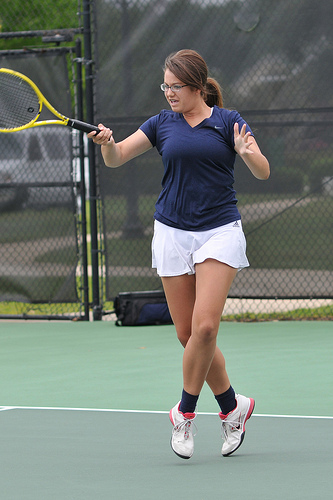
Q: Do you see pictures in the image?
A: No, there are no pictures.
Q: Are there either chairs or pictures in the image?
A: No, there are no pictures or chairs.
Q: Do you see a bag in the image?
A: Yes, there is a bag.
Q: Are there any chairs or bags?
A: Yes, there is a bag.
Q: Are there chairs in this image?
A: No, there are no chairs.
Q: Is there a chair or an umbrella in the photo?
A: No, there are no chairs or umbrellas.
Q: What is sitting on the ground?
A: The bag is sitting on the ground.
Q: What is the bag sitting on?
A: The bag is sitting on the ground.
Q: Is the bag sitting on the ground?
A: Yes, the bag is sitting on the ground.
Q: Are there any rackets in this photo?
A: Yes, there is a racket.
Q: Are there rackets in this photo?
A: Yes, there is a racket.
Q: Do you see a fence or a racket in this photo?
A: Yes, there is a racket.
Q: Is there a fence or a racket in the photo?
A: Yes, there is a racket.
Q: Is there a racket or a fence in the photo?
A: Yes, there is a racket.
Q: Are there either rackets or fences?
A: Yes, there is a racket.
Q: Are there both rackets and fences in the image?
A: Yes, there are both a racket and a fence.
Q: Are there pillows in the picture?
A: No, there are no pillows.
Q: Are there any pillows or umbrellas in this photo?
A: No, there are no pillows or umbrellas.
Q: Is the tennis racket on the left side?
A: Yes, the tennis racket is on the left of the image.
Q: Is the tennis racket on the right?
A: No, the tennis racket is on the left of the image.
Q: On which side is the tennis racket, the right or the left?
A: The tennis racket is on the left of the image.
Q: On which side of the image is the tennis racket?
A: The tennis racket is on the left of the image.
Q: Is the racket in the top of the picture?
A: Yes, the racket is in the top of the image.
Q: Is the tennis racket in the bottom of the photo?
A: No, the tennis racket is in the top of the image.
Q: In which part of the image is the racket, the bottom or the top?
A: The racket is in the top of the image.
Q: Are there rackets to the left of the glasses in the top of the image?
A: Yes, there is a racket to the left of the glasses.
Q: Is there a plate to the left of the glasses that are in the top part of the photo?
A: No, there is a racket to the left of the glasses.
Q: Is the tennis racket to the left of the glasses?
A: Yes, the tennis racket is to the left of the glasses.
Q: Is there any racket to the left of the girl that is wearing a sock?
A: Yes, there is a racket to the left of the girl.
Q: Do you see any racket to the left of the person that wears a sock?
A: Yes, there is a racket to the left of the girl.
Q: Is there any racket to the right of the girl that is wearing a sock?
A: No, the racket is to the left of the girl.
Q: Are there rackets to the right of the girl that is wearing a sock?
A: No, the racket is to the left of the girl.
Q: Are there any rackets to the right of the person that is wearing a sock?
A: No, the racket is to the left of the girl.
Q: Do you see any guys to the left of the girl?
A: No, there is a racket to the left of the girl.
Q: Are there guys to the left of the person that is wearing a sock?
A: No, there is a racket to the left of the girl.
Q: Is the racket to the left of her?
A: Yes, the racket is to the left of the girl.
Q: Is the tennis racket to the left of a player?
A: No, the tennis racket is to the left of the girl.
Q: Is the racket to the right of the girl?
A: No, the racket is to the left of the girl.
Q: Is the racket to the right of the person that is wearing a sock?
A: No, the racket is to the left of the girl.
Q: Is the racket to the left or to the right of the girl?
A: The racket is to the left of the girl.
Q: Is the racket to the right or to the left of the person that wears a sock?
A: The racket is to the left of the girl.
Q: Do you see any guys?
A: No, there are no guys.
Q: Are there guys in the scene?
A: No, there are no guys.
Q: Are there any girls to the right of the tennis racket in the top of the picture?
A: Yes, there is a girl to the right of the racket.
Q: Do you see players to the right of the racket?
A: No, there is a girl to the right of the racket.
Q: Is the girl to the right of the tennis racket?
A: Yes, the girl is to the right of the tennis racket.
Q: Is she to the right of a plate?
A: No, the girl is to the right of the tennis racket.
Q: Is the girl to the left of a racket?
A: No, the girl is to the right of a racket.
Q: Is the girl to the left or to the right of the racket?
A: The girl is to the right of the racket.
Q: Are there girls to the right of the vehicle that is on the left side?
A: Yes, there is a girl to the right of the vehicle.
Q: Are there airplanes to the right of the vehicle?
A: No, there is a girl to the right of the vehicle.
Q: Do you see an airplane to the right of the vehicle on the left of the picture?
A: No, there is a girl to the right of the vehicle.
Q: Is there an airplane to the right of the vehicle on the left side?
A: No, there is a girl to the right of the vehicle.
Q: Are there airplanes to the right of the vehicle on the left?
A: No, there is a girl to the right of the vehicle.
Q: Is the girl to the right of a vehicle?
A: Yes, the girl is to the right of a vehicle.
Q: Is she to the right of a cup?
A: No, the girl is to the right of a vehicle.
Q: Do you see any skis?
A: No, there are no skis.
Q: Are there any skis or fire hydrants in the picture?
A: No, there are no skis or fire hydrants.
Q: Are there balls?
A: No, there are no balls.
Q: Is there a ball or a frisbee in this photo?
A: No, there are no balls or frisbees.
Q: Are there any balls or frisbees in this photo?
A: No, there are no balls or frisbees.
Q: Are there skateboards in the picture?
A: No, there are no skateboards.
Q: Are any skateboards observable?
A: No, there are no skateboards.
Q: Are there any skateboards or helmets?
A: No, there are no skateboards or helmets.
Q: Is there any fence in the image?
A: Yes, there is a fence.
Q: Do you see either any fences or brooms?
A: Yes, there is a fence.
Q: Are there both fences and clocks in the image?
A: No, there is a fence but no clocks.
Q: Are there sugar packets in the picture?
A: No, there are no sugar packets.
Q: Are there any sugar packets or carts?
A: No, there are no sugar packets or carts.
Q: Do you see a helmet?
A: No, there are no helmets.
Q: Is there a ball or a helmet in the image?
A: No, there are no helmets or balls.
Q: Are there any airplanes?
A: No, there are no airplanes.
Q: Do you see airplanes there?
A: No, there are no airplanes.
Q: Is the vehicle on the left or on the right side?
A: The vehicle is on the left of the image.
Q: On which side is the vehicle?
A: The vehicle is on the left of the image.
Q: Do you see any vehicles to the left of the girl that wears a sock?
A: Yes, there is a vehicle to the left of the girl.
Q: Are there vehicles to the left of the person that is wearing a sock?
A: Yes, there is a vehicle to the left of the girl.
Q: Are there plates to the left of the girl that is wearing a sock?
A: No, there is a vehicle to the left of the girl.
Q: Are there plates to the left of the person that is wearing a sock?
A: No, there is a vehicle to the left of the girl.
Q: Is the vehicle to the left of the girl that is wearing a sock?
A: Yes, the vehicle is to the left of the girl.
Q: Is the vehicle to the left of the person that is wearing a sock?
A: Yes, the vehicle is to the left of the girl.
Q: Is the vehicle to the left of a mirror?
A: No, the vehicle is to the left of the girl.